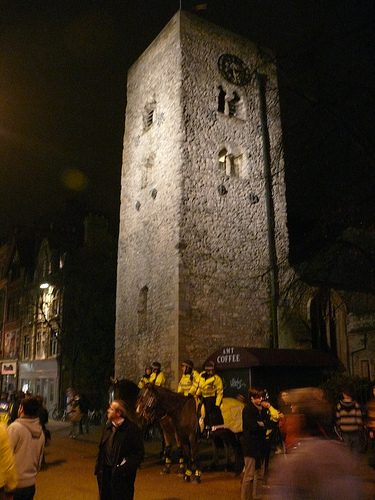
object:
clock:
[218, 51, 251, 86]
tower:
[113, 6, 293, 389]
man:
[92, 399, 141, 498]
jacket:
[94, 418, 142, 478]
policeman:
[188, 361, 225, 436]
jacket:
[194, 372, 223, 404]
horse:
[138, 381, 244, 483]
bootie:
[193, 468, 203, 480]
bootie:
[183, 468, 195, 478]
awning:
[199, 343, 349, 369]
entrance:
[308, 285, 348, 376]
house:
[0, 211, 117, 412]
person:
[7, 392, 49, 498]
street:
[4, 442, 240, 498]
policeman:
[177, 356, 199, 395]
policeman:
[146, 358, 167, 387]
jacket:
[146, 370, 167, 386]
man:
[238, 385, 270, 498]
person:
[331, 383, 365, 447]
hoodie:
[332, 398, 364, 432]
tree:
[255, 221, 372, 344]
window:
[216, 147, 230, 174]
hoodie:
[6, 416, 48, 488]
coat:
[241, 402, 269, 458]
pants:
[94, 469, 135, 498]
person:
[61, 396, 84, 436]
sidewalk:
[46, 418, 167, 456]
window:
[229, 151, 242, 176]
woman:
[275, 400, 309, 455]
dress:
[278, 416, 305, 453]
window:
[136, 286, 149, 334]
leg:
[187, 428, 203, 482]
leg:
[179, 430, 193, 481]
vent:
[142, 104, 156, 129]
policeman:
[139, 363, 153, 391]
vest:
[138, 377, 150, 390]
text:
[214, 351, 243, 365]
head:
[140, 379, 164, 424]